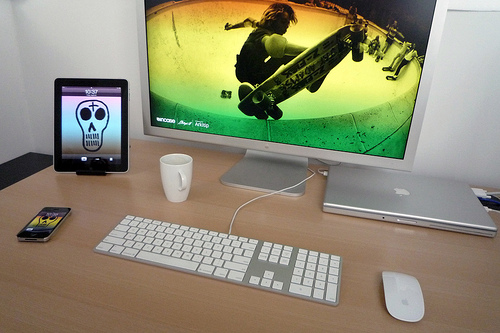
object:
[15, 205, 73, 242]
phone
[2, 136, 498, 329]
desk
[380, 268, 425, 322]
mouse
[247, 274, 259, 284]
key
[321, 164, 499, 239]
laptop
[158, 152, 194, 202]
cup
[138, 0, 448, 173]
monitor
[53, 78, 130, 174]
tablet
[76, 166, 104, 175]
stand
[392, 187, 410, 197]
logo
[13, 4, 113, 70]
wall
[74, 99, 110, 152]
skull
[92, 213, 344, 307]
keyboard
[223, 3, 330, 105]
man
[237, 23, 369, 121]
skateboard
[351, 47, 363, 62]
wheel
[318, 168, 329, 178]
cord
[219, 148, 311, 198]
stand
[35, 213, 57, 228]
skull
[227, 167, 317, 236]
cord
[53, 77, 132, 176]
ipad